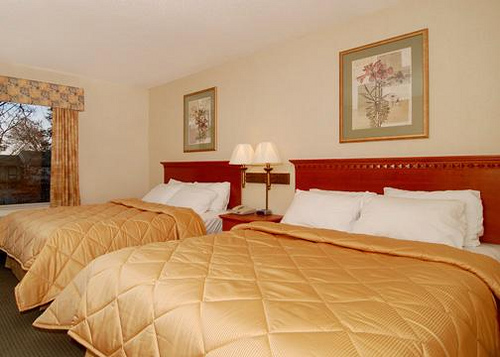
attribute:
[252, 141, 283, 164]
lampshade — white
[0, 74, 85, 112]
valance — tan, gray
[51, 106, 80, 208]
drape — tan, beige, gold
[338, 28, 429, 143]
picture — framed, matted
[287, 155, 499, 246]
headboard — wooden, red, queen size, cherry stained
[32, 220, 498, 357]
comforter — gold, queen size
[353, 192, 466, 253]
pillow — white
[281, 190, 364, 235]
pillow — white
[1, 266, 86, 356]
carpet — olive, grey, green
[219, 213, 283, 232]
end table — wooden, red, wood, cherry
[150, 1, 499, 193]
wall — beige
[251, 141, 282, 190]
lamp — gold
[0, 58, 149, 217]
wall — beige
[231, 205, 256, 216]
phone — off-white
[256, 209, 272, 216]
clock — small, grey